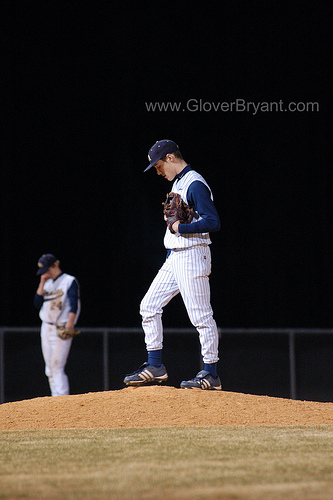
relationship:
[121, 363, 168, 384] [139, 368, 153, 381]
sneaker has stripes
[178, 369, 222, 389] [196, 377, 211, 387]
sneaker has stripes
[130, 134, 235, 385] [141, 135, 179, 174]
man wearing hat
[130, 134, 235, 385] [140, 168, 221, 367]
man wearing uniform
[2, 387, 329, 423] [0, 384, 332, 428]
dirt in mound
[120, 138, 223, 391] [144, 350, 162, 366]
pitcher wearing sock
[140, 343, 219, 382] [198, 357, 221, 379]
socks wearing sock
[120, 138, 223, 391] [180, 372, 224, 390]
pitcher wearing shoe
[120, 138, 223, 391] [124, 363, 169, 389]
pitcher wearing shoe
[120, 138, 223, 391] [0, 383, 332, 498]
pitcher standing on mound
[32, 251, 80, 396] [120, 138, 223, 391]
player near pitcher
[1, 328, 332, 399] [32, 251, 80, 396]
fence behind player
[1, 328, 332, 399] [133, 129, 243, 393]
fence behind player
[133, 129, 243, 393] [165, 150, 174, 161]
player has ear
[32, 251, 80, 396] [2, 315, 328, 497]
player on ball field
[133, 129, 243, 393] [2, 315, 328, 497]
player on ball field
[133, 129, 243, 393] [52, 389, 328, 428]
player on hill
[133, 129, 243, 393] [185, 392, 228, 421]
player on dirt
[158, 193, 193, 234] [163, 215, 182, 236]
baseball mitt in player's hand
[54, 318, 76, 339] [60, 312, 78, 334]
baseball mitt in player's hand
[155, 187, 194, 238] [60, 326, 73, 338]
mitt in hand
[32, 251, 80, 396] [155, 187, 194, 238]
player has mitt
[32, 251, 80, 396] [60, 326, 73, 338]
player has hand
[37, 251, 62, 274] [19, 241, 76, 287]
cap on head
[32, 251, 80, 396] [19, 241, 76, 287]
player has head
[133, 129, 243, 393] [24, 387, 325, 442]
player standing on dirt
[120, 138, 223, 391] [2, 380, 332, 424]
pitcher standing on pitcher's mound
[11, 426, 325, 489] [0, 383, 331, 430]
grass in front of pitchers mound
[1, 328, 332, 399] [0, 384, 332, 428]
fence behind mound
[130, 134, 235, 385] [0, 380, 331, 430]
man standing on pitcher's mound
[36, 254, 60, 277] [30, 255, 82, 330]
head of baseball player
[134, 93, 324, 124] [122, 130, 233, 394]
lettering above pitcher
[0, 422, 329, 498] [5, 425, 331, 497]
turf on field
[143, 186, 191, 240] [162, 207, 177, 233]
glove on hand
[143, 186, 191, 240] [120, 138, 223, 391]
glove on pitcher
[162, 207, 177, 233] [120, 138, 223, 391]
hand of pitcher